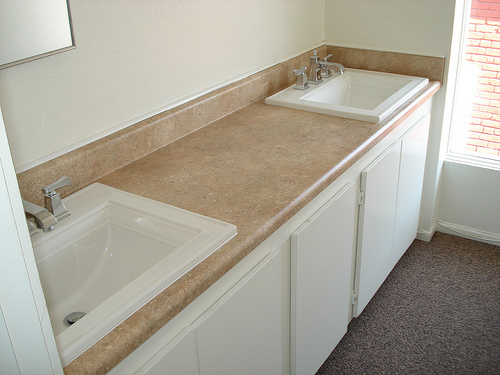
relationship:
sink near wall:
[271, 60, 428, 115] [334, 3, 449, 40]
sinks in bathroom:
[21, 177, 242, 364] [2, 3, 482, 372]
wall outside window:
[462, 17, 497, 167] [434, 6, 498, 169]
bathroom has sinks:
[2, 2, 500, 374] [263, 44, 428, 119]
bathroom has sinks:
[2, 2, 500, 374] [21, 177, 242, 364]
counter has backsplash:
[142, 100, 345, 213] [11, 31, 444, 221]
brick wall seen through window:
[472, 24, 497, 146] [439, 1, 483, 167]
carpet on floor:
[312, 232, 499, 372] [307, 222, 479, 369]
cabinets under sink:
[174, 118, 428, 373] [287, 42, 443, 154]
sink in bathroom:
[287, 42, 443, 154] [2, 3, 482, 372]